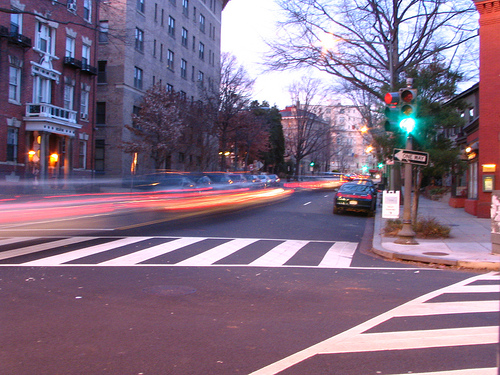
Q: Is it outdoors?
A: Yes, it is outdoors.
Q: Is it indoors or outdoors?
A: It is outdoors.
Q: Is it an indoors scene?
A: No, it is outdoors.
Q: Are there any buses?
A: No, there are no buses.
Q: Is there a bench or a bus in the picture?
A: No, there are no buses or benches.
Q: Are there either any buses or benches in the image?
A: No, there are no buses or benches.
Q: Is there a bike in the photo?
A: No, there are no bikes.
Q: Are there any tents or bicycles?
A: No, there are no bicycles or tents.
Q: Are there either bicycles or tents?
A: No, there are no bicycles or tents.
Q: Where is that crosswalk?
A: The crosswalk is on the street.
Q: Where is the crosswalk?
A: The crosswalk is on the street.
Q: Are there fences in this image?
A: No, there are no fences.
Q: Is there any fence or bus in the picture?
A: No, there are no fences or buses.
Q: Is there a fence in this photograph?
A: No, there are no fences.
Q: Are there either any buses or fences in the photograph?
A: No, there are no fences or buses.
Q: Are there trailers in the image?
A: No, there are no trailers.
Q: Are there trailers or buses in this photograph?
A: No, there are no trailers or buses.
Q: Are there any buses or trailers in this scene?
A: No, there are no trailers or buses.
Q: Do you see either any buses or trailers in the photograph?
A: No, there are no trailers or buses.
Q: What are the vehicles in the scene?
A: The vehicles are cars.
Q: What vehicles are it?
A: The vehicles are cars.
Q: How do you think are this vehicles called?
A: These are cars.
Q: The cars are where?
A: The cars are on the road.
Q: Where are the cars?
A: The cars are on the road.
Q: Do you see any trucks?
A: No, there are no trucks.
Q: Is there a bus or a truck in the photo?
A: No, there are no trucks or buses.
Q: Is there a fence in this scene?
A: No, there are no fences.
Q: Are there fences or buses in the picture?
A: No, there are no fences or buses.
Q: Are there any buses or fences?
A: No, there are no fences or buses.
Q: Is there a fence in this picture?
A: No, there are no fences.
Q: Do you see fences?
A: No, there are no fences.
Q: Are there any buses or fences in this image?
A: No, there are no fences or buses.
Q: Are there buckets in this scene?
A: No, there are no buckets.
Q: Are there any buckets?
A: No, there are no buckets.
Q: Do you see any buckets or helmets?
A: No, there are no buckets or helmets.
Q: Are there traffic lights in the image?
A: Yes, there is a traffic light.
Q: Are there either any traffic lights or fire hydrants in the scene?
A: Yes, there is a traffic light.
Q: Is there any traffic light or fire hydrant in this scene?
A: Yes, there is a traffic light.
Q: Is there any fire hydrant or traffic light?
A: Yes, there is a traffic light.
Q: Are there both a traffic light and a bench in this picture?
A: No, there is a traffic light but no benches.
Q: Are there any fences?
A: No, there are no fences.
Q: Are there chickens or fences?
A: No, there are no fences or chickens.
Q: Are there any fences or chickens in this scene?
A: No, there are no fences or chickens.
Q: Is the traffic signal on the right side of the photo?
A: Yes, the traffic signal is on the right of the image.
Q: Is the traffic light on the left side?
A: No, the traffic light is on the right of the image.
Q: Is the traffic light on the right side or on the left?
A: The traffic light is on the right of the image.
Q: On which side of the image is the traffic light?
A: The traffic light is on the right of the image.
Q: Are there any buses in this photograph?
A: No, there are no buses.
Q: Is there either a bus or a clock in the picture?
A: No, there are no buses or clocks.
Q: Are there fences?
A: No, there are no fences.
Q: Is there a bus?
A: No, there are no buses.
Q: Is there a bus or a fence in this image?
A: No, there are no buses or fences.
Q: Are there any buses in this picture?
A: No, there are no buses.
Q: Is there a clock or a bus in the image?
A: No, there are no buses or clocks.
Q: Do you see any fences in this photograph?
A: No, there are no fences.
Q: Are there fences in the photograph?
A: No, there are no fences.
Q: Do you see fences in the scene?
A: No, there are no fences.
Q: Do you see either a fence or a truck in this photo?
A: No, there are no fences or trucks.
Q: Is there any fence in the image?
A: No, there are no fences.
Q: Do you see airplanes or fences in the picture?
A: No, there are no fences or airplanes.